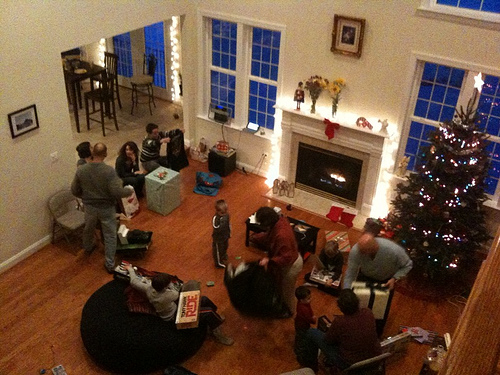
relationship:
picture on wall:
[327, 10, 367, 60] [187, 1, 488, 202]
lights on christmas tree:
[429, 169, 470, 211] [373, 92, 499, 311]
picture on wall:
[9, 108, 38, 126] [0, 3, 187, 263]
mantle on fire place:
[275, 99, 400, 139] [262, 104, 390, 234]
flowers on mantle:
[274, 66, 355, 130] [275, 99, 400, 139]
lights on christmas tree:
[440, 122, 479, 153] [384, 72, 500, 289]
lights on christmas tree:
[416, 162, 443, 187] [384, 72, 500, 289]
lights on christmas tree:
[410, 221, 465, 251] [384, 72, 500, 289]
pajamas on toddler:
[210, 212, 230, 265] [210, 196, 234, 269]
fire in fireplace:
[329, 170, 346, 182] [298, 156, 357, 201]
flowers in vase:
[301, 74, 327, 102] [310, 102, 315, 114]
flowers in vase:
[324, 78, 345, 99] [329, 104, 337, 120]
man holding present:
[340, 233, 410, 331] [348, 277, 400, 326]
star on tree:
[473, 72, 485, 92] [373, 70, 493, 300]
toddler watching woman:
[210, 196, 234, 269] [253, 207, 302, 317]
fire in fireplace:
[330, 173, 347, 183] [269, 96, 394, 226]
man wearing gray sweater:
[340, 233, 414, 339] [337, 235, 414, 291]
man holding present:
[340, 233, 414, 339] [403, 117, 488, 274]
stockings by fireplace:
[324, 201, 359, 229] [287, 134, 368, 211]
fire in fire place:
[330, 173, 347, 183] [262, 104, 392, 234]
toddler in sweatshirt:
[210, 196, 234, 269] [200, 203, 238, 243]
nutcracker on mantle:
[291, 74, 314, 118] [278, 105, 398, 162]